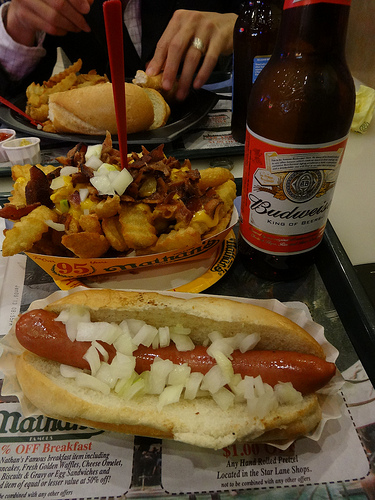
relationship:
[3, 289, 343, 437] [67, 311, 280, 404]
hot dog topped with onions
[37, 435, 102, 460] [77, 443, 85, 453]
breakfast colored red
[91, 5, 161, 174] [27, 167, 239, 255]
fork in fries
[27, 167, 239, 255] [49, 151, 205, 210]
fries have various toppings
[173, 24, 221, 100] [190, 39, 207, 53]
finger has on it a ring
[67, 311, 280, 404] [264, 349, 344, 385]
onions are on top of meat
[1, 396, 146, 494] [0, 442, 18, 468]
coupon has percentage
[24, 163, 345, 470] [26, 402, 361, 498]
food on paper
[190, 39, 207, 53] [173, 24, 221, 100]
ring on finger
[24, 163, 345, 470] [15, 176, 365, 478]
food on a plate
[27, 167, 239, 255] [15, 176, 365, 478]
fries are on plate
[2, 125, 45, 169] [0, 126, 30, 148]
cups are filled with sauce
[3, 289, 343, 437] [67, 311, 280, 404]
hot dog has onions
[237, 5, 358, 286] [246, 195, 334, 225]
bottle labeled budweiser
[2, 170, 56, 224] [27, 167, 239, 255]
bacon on top of fries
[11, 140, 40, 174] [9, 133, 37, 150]
paper has mustard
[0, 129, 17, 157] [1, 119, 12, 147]
paper has ketchup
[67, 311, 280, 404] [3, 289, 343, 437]
onions are on hot dog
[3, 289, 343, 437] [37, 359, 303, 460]
hot dog on a bun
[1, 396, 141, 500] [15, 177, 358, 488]
coupon are on placemat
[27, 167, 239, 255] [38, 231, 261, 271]
french fries are in paper basket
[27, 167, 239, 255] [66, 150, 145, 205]
french fries are covered with onions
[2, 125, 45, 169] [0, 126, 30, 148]
cups have mustard and ketchup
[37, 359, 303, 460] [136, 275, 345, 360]
bun in a paper dish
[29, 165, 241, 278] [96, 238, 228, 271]
container says nathan's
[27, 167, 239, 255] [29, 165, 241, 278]
french fries are in a container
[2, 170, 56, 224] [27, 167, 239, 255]
bacon topping french fries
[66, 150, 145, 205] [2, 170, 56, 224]
onions are on top of bacon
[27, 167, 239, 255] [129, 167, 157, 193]
french fries have cheese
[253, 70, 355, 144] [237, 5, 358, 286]
beer in a bottle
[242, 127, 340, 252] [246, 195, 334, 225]
label has on it word budweiser